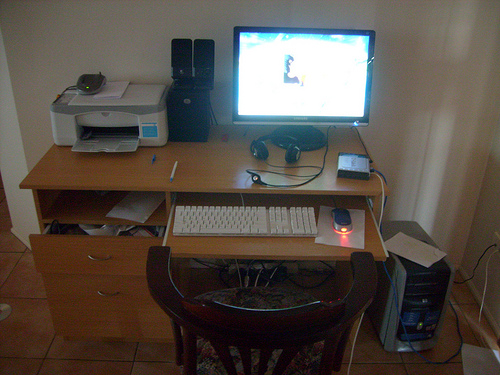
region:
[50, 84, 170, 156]
Computer printer on desktop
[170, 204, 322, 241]
White computer keyboard on desk shelf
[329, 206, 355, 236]
Wireless mouse on desktop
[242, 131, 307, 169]
Audio headphones on desk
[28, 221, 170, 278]
Open drawer on computer desk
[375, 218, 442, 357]
Computer tower on floor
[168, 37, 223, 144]
Computer audio system on desk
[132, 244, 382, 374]
Wooden chair for desk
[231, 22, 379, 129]
Illuminated computer monitor on desk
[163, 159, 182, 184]
Ball point pen on desk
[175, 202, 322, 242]
White computer keyboard with a gray background and white keys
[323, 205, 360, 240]
Dark gray and light gray computer mouse with a red light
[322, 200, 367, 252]
Gray mouse pad on a light brown wooden desk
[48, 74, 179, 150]
Gray and off white computer printer with a blue sign on it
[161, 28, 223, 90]
Twin dark black speakers in front of a white wall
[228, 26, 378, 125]
Black computer monitor with a bright screen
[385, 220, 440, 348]
Gray and black computer with a green light and white paper on top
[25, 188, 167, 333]
Light brown drawers of a desk with gray metal handles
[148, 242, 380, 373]
Dark colored wooden computer chair with padding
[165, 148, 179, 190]
White pen with a blue cap on a brown computer desk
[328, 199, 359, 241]
Blue and silver mouse next to the keyboard.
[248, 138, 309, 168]
Blue and silver mouse next to the keyboard.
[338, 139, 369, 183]
Blue and silver mouse next to the keyboard.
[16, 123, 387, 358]
wooden computer desk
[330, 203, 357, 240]
lit up computer mouse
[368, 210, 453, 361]
computer tower on the floor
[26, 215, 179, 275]
open top drawer on a desk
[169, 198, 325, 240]
white keyboard for a computer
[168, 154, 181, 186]
ink pen on a desk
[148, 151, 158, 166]
blue cap for a pen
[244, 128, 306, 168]
black headphones sitting on a desk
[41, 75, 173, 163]
computer printer on a desk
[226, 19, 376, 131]
glowing computer monitor on a desk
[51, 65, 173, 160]
a printer on the top of a desk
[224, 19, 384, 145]
a monitor on the top of a desk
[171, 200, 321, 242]
a computer keyboard on top of a desk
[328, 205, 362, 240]
a computer mouse on top of a desk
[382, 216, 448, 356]
a computer sitting on a the floor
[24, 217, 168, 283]
an open drawer of a desk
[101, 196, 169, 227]
a paper in the slot of a desk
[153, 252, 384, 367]
a wooden chair in front of a desk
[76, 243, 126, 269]
a handle of a drawer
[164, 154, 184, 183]
a pen on the top of a desk